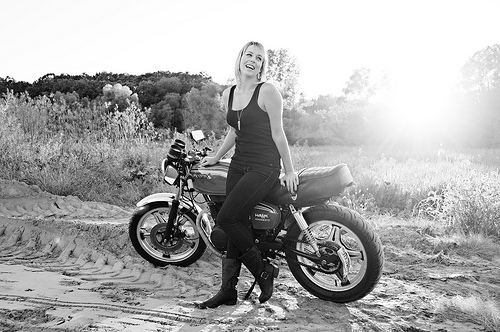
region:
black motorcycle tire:
[282, 198, 392, 308]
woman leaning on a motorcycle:
[96, 31, 408, 308]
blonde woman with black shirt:
[200, 35, 302, 193]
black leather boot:
[231, 245, 286, 310]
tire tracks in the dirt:
[16, 210, 117, 312]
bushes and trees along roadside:
[13, 62, 115, 269]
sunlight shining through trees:
[340, 48, 496, 213]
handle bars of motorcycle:
[156, 120, 214, 210]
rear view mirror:
[155, 158, 195, 190]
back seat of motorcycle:
[297, 161, 359, 202]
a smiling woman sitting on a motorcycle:
[194, 39, 300, 315]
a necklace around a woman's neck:
[232, 79, 247, 131]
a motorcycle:
[119, 138, 395, 304]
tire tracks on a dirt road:
[2, 225, 134, 281]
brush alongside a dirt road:
[1, 87, 153, 199]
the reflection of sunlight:
[363, 28, 466, 158]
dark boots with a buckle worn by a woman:
[203, 249, 281, 307]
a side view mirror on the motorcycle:
[161, 164, 183, 184]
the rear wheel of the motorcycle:
[282, 202, 386, 303]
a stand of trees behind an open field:
[5, 72, 222, 127]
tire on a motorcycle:
[277, 200, 382, 308]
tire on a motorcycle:
[122, 192, 212, 272]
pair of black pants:
[202, 163, 283, 285]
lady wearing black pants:
[185, 36, 304, 313]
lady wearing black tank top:
[176, 36, 297, 313]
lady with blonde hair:
[161, 33, 315, 315]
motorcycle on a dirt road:
[114, 114, 392, 308]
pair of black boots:
[191, 245, 285, 317]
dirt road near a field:
[1, 174, 498, 330]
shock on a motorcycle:
[289, 202, 319, 259]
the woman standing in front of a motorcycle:
[201, 43, 301, 309]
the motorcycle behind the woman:
[126, 129, 383, 302]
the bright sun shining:
[348, 2, 498, 163]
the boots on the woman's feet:
[198, 245, 280, 308]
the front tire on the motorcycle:
[128, 198, 207, 266]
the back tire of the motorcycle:
[286, 204, 382, 304]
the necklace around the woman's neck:
[230, 83, 257, 129]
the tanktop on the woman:
[225, 81, 280, 168]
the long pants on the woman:
[212, 156, 284, 256]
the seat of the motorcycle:
[263, 161, 352, 206]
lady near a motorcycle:
[185, 38, 298, 316]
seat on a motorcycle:
[276, 163, 356, 208]